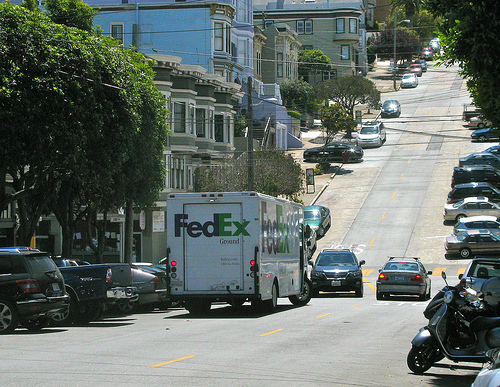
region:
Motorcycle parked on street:
[386, 256, 498, 377]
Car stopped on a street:
[351, 247, 433, 367]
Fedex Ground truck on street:
[163, 182, 314, 337]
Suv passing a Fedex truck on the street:
[216, 246, 396, 322]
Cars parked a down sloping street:
[348, 30, 443, 205]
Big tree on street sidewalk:
[16, 40, 176, 376]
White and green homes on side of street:
[138, 42, 403, 256]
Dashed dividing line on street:
[380, 115, 436, 250]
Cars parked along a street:
[433, 137, 498, 265]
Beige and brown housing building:
[273, 8, 472, 110]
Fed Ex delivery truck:
[164, 191, 311, 311]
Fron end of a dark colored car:
[308, 247, 365, 299]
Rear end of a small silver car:
[374, 253, 432, 299]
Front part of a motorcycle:
[398, 293, 478, 370]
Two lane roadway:
[354, 161, 433, 243]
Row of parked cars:
[445, 143, 498, 259]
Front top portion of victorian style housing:
[148, 56, 245, 193]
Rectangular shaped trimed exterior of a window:
[333, 16, 345, 36]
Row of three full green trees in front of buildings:
[3, 3, 161, 250]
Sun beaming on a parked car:
[380, 98, 400, 120]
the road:
[291, 34, 402, 225]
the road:
[198, 355, 250, 385]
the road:
[115, 290, 295, 384]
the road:
[41, 227, 239, 379]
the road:
[155, 262, 287, 366]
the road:
[207, 320, 298, 382]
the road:
[195, 280, 313, 378]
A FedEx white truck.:
[161, 179, 323, 314]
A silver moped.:
[404, 266, 496, 374]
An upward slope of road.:
[307, 6, 477, 303]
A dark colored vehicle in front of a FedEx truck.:
[297, 228, 371, 306]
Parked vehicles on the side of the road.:
[418, 96, 495, 386]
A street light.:
[389, 8, 410, 91]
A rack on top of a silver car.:
[386, 246, 426, 263]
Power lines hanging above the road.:
[66, 6, 489, 160]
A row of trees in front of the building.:
[2, 3, 169, 291]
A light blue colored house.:
[82, 0, 320, 159]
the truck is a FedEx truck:
[159, 185, 317, 319]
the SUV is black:
[298, 242, 370, 299]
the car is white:
[373, 250, 433, 305]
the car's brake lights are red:
[377, 268, 424, 284]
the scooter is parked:
[401, 265, 497, 375]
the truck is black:
[50, 257, 140, 322]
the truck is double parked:
[162, 185, 317, 312]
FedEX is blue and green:
[171, 208, 257, 244]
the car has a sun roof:
[436, 190, 498, 220]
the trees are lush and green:
[3, 4, 175, 281]